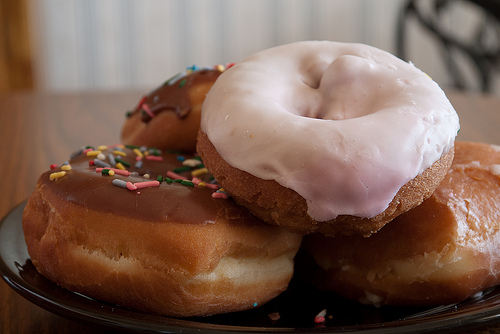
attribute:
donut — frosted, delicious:
[195, 39, 462, 242]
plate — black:
[3, 191, 500, 334]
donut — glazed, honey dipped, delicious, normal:
[307, 138, 497, 312]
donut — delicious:
[23, 141, 305, 320]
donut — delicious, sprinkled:
[117, 63, 232, 157]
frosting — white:
[197, 39, 463, 225]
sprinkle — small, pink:
[134, 180, 163, 191]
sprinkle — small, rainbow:
[111, 177, 128, 189]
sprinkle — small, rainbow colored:
[180, 178, 196, 187]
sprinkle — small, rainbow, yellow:
[47, 171, 67, 184]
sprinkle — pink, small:
[142, 103, 155, 122]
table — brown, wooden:
[2, 87, 500, 333]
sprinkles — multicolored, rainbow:
[48, 142, 233, 203]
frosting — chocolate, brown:
[39, 145, 256, 227]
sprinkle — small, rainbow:
[108, 167, 134, 178]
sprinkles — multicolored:
[124, 60, 238, 119]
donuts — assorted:
[20, 38, 499, 317]